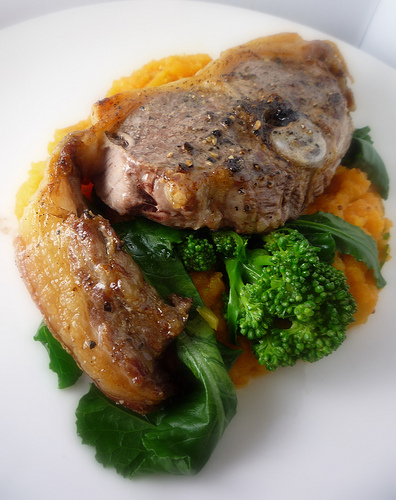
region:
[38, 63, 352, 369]
food on a plate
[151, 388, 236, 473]
green leaf on plate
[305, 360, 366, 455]
white plate under food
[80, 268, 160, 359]
brown food on plate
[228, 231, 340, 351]
green food on plate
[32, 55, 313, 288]
two pieces of meat on plate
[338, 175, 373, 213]
orange food on plate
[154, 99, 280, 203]
spices on food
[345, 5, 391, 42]
white wall next to food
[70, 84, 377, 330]
different colored food on plate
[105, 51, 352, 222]
Filet mignon steak on a plate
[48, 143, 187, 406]
Strip of bacon around steak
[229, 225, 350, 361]
Bright green broccoli floret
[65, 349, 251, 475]
Piece of green leafy spinach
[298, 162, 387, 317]
Pile of mashed sweet potatoes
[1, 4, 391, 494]
Large white dinner plate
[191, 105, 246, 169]
Peppercorns on steak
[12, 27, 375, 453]
Compete meal in one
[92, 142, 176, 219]
Fat on edge of steak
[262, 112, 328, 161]
Round bone on steak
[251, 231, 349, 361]
a piece of broccolli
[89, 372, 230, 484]
a piece of lettuce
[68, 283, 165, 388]
a piece of bacon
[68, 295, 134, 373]
pepper on a piece of bacon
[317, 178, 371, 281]
sweet potato under meat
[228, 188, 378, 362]
sweet potato and broccoli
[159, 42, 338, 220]
meat with a bone in it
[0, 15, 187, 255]
white plate under meat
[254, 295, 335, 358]
small green broccoli piece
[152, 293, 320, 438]
lettuce and broccoli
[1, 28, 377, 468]
dinner entree on plate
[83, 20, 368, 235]
piece of meat on top of pile of food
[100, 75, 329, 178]
bones set into edges of meat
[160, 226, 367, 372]
florets or broccoli rabe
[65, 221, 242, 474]
dark green leaf draping onto plate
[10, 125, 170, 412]
shiny fat on end of cooked meat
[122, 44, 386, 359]
mashed sweet potatoes under food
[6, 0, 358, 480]
meal centered on white plate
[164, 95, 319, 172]
condiments sprinkled over browned meat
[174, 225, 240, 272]
tightly closed buds of very green broccoli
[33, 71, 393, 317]
Food on a plate.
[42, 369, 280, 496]
Green lettuce with the food.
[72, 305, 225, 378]
Pepper on the food.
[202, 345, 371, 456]
White plate under the food.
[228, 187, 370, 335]
Green broccoli on the plate.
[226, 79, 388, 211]
Bone in the meat.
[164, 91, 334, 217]
Seasoning on the meat.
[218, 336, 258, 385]
Orange food under the meat.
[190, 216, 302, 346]
Stem of the broccoli.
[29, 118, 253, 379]
Fatty part of the meat.